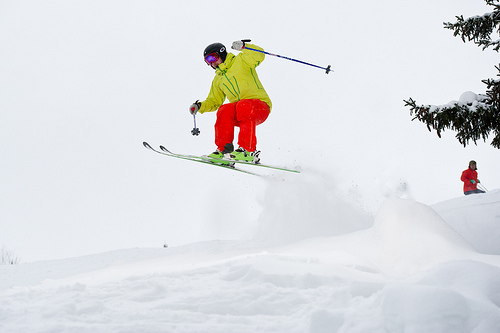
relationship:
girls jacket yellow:
[192, 41, 271, 115] [190, 41, 271, 118]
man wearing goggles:
[142, 39, 331, 181] [205, 53, 224, 65]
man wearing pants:
[142, 39, 331, 181] [213, 98, 271, 160]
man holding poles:
[142, 39, 331, 181] [185, 39, 335, 138]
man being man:
[142, 39, 331, 181] [457, 159, 487, 198]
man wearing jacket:
[142, 39, 331, 181] [190, 41, 271, 118]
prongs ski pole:
[191, 64, 331, 135] [185, 39, 335, 138]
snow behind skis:
[1, 184, 497, 331] [142, 135, 299, 181]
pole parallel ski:
[233, 37, 335, 79] [159, 141, 302, 176]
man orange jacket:
[457, 159, 487, 198] [462, 172, 480, 191]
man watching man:
[457, 159, 487, 198] [142, 39, 331, 181]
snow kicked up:
[1, 184, 497, 331] [261, 169, 422, 235]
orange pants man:
[213, 98, 271, 160] [142, 39, 331, 181]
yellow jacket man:
[190, 41, 271, 118] [142, 39, 331, 181]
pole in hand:
[233, 37, 335, 79] [229, 40, 247, 52]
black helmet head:
[202, 43, 230, 69] [204, 44, 230, 72]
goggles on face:
[205, 53, 224, 65] [204, 42, 230, 69]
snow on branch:
[406, 1, 499, 149] [405, 0, 500, 148]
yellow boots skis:
[205, 148, 263, 167] [142, 135, 299, 181]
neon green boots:
[202, 148, 263, 167] [205, 148, 263, 167]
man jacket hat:
[457, 159, 487, 198] [468, 162, 479, 171]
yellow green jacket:
[190, 41, 271, 118] [462, 172, 480, 191]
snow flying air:
[1, 184, 497, 331] [0, 0, 497, 215]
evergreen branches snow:
[405, 2, 500, 154] [406, 1, 499, 149]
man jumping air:
[142, 39, 331, 181] [0, 0, 497, 215]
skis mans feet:
[142, 135, 299, 181] [205, 148, 263, 167]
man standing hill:
[457, 159, 487, 198] [0, 183, 499, 331]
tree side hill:
[405, 0, 500, 148] [403, 1, 499, 331]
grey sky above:
[0, 0, 496, 185] [0, 0, 497, 215]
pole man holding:
[233, 37, 335, 79] [229, 40, 247, 52]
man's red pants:
[142, 39, 331, 181] [213, 98, 271, 160]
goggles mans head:
[205, 53, 224, 65] [204, 44, 230, 72]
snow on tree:
[406, 1, 499, 149] [412, 6, 485, 158]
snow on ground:
[1, 184, 497, 331] [128, 239, 422, 329]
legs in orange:
[213, 98, 271, 160] [213, 98, 271, 160]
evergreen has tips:
[405, 2, 500, 154] [397, 90, 427, 126]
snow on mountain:
[1, 184, 497, 331] [4, 183, 496, 332]